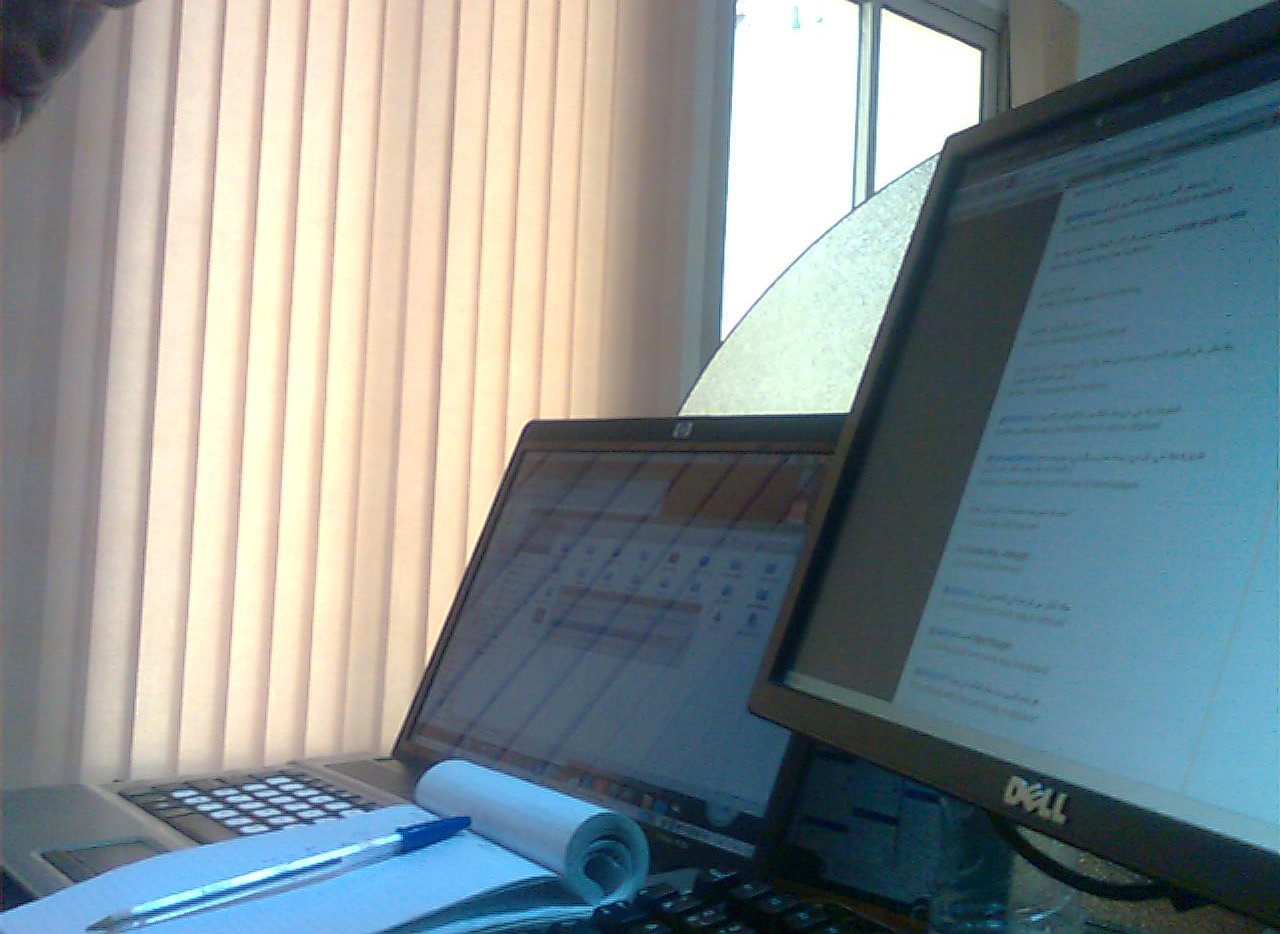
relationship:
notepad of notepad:
[4, 753, 646, 928] [4, 753, 646, 928]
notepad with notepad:
[4, 753, 646, 928] [4, 753, 646, 928]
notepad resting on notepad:
[4, 753, 646, 928] [4, 753, 646, 928]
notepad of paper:
[4, 753, 646, 928] [10, 726, 656, 921]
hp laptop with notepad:
[4, 412, 894, 916] [4, 753, 646, 928]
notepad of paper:
[4, 753, 646, 928] [1, 754, 661, 921]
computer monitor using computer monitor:
[762, 16, 1276, 921] [762, 10, 1276, 921]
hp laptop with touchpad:
[3, 412, 894, 917] [43, 837, 203, 871]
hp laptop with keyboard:
[3, 412, 894, 917] [92, 735, 378, 865]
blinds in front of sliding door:
[10, 0, 754, 788] [3, 2, 992, 781]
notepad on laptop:
[3, 753, 666, 929] [1, 393, 871, 916]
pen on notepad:
[82, 809, 477, 927] [3, 753, 666, 929]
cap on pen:
[394, 802, 477, 853] [82, 809, 477, 927]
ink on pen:
[129, 847, 340, 923] [82, 809, 477, 927]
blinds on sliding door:
[0, 0, 756, 787] [4, 1, 993, 780]